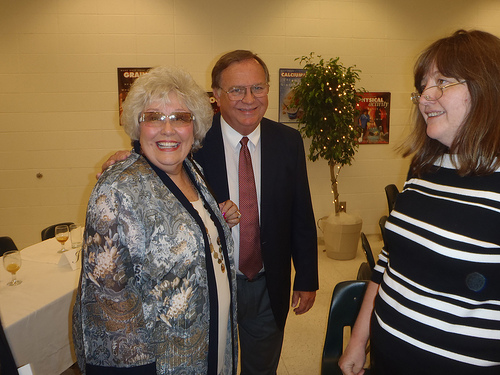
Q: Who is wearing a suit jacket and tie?
A: The man with glasses.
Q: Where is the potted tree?
A: In the back near the wall.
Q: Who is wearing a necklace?
A: The woman on the left.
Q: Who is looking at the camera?
A: The man and woman on the left.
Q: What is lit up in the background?
A: The tree.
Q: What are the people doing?
A: Smiling.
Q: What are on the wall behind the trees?
A: Two posters.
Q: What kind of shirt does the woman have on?
A: Striped shirt.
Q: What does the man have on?
A: Suit jacket.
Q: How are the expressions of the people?
A: Happy.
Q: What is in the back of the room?
A: Tree.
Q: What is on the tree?
A: Lights.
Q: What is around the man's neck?
A: Tie.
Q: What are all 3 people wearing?
A: Glasses.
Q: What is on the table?
A: Glasses.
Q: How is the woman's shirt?
A: Striped.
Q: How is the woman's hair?
A: Brown.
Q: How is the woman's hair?
A: Grey.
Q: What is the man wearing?
A: Coat.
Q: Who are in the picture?
A: People.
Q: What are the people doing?
A: Socializing.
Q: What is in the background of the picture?
A: Christmas tree.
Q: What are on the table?
A: Glasses.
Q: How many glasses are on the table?
A: Two.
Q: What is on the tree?
A: Lights.